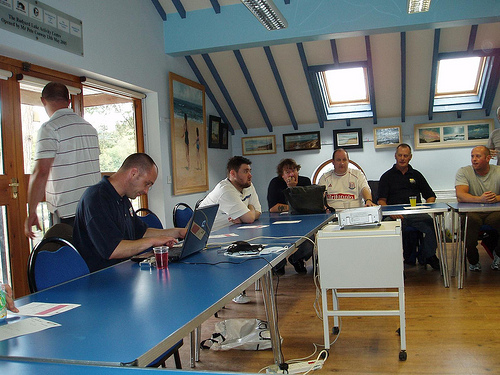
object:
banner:
[1, 0, 87, 57]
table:
[0, 202, 340, 367]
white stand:
[318, 219, 407, 361]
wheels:
[392, 348, 406, 361]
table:
[47, 278, 155, 365]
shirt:
[377, 164, 440, 209]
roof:
[155, 22, 486, 137]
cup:
[153, 246, 170, 271]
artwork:
[166, 68, 210, 196]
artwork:
[241, 134, 277, 156]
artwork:
[282, 131, 322, 152]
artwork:
[332, 127, 364, 149]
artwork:
[374, 125, 402, 148]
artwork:
[412, 117, 496, 150]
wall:
[226, 128, 496, 195]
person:
[192, 127, 203, 172]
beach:
[173, 114, 204, 189]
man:
[453, 144, 496, 273]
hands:
[481, 188, 496, 202]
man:
[23, 80, 105, 276]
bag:
[284, 184, 335, 214]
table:
[2, 195, 499, 374]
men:
[22, 73, 104, 248]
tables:
[2, 173, 354, 355]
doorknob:
[8, 179, 18, 199]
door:
[0, 79, 26, 300]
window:
[315, 62, 375, 121]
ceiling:
[164, 1, 499, 121]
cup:
[409, 195, 416, 208]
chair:
[25, 237, 94, 290]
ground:
[344, 147, 385, 174]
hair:
[224, 148, 252, 171]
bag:
[200, 316, 285, 351]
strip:
[261, 253, 351, 373]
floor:
[156, 238, 498, 373]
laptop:
[128, 204, 222, 264]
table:
[6, 195, 347, 374]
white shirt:
[198, 179, 264, 233]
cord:
[253, 229, 297, 246]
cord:
[224, 252, 273, 269]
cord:
[300, 334, 325, 361]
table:
[152, 265, 264, 325]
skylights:
[425, 50, 497, 114]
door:
[1, 65, 149, 307]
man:
[376, 140, 443, 274]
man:
[194, 150, 261, 303]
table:
[53, 243, 301, 372]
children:
[179, 108, 193, 171]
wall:
[131, 41, 256, 249]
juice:
[408, 196, 418, 208]